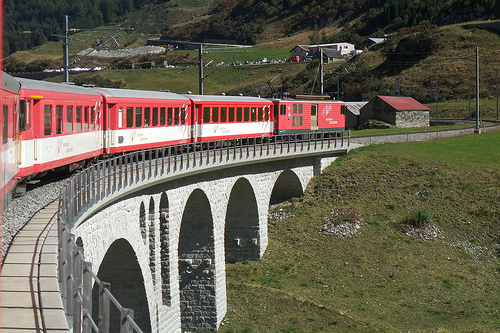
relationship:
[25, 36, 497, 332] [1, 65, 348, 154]
grass under train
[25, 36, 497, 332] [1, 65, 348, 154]
grass below train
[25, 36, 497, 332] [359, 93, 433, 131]
grass below building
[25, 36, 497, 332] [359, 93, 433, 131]
grass under building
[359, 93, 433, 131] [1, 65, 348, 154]
building beside train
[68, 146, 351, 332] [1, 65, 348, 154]
bridge under train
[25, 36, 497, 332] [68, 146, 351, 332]
grass near bridge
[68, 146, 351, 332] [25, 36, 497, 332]
bridge near grass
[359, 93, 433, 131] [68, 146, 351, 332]
building near bridge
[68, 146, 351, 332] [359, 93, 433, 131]
bridge near building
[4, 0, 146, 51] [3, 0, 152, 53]
forest filled with trees